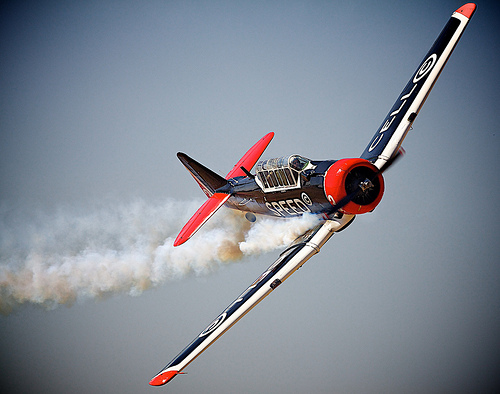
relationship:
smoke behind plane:
[2, 194, 312, 313] [173, 1, 477, 347]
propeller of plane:
[321, 141, 407, 224] [173, 1, 477, 347]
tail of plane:
[174, 132, 276, 246] [173, 1, 477, 347]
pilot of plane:
[289, 154, 311, 173] [173, 1, 477, 347]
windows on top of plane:
[257, 154, 311, 192] [173, 1, 477, 347]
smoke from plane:
[2, 194, 312, 313] [173, 1, 477, 347]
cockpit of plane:
[249, 154, 313, 190] [173, 1, 477, 347]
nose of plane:
[325, 157, 387, 216] [173, 1, 477, 347]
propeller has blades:
[321, 141, 407, 224] [310, 142, 411, 234]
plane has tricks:
[173, 1, 477, 347] [108, 0, 498, 392]